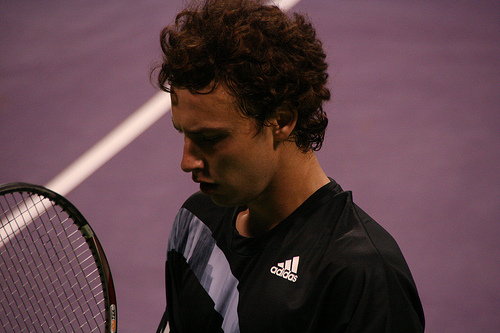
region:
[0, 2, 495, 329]
professional tennis player displaying emotion in between points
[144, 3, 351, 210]
concentrating face of professional tennis player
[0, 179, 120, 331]
partial view of tennis racquet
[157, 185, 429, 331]
adidas tennis shirt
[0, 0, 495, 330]
hard tennis court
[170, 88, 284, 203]
face of tennis player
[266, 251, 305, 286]
adidas logo on tennis shirt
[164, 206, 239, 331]
grey stripe on tennis shirt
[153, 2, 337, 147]
curly brown hair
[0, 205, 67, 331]
tennis racquet strings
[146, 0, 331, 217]
the head of a man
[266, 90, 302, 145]
the ear of a man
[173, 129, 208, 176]
the nose of a man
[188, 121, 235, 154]
the eye of a man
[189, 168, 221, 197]
the mouth of a man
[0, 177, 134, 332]
a tennis racket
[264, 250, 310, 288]
a logo on the shirt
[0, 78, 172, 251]
a white stripe on the court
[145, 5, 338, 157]
the hair of a man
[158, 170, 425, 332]
a black shirt on the man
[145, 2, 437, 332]
white male tennis player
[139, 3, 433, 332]
young slender white man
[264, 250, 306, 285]
adidas logo on black shirt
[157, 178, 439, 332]
black and gray sports shirt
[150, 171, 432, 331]
black shirt with gray stripe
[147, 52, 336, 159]
perspiration in hair along hairline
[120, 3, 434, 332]
man with head tilted down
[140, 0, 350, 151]
short brown curly hair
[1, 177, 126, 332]
brown and silver tennis racket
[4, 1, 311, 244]
white boundary line on tennis court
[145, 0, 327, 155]
Brown long curly hair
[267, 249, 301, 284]
White Adidas logo on shirt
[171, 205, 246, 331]
Lilac stripe on black shirt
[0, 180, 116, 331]
Tennis racket in front of man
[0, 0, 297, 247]
White stripe on tennis court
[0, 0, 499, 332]
Tennis court is purple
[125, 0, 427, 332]
Young man is frowning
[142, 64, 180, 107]
Brown curl dropped on forehead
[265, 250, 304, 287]
White Adidas logo near stripe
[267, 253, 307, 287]
White Adidas logo near neck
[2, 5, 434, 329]
man playing tennis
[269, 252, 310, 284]
small white Adidas logo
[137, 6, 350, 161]
brown curly hair on the head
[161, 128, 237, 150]
eyes looking down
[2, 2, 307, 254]
white line on the court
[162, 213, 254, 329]
gray stripe on the shirt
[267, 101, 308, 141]
ear poking out from under the curly hair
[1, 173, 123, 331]
top of a tennis racket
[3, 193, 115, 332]
strings on the tennis racket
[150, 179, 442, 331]
black, gray, and white shirt